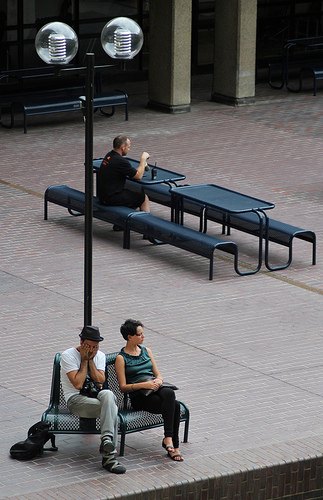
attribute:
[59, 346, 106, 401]
shirt — short sleeve, white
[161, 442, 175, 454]
sandal — open toed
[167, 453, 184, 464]
sandal — open toed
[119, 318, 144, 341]
hair — black, dark, short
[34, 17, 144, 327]
lamp post — black, tall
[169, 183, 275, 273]
table — picnic table, metal, green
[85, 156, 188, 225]
table — metal, green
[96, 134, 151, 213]
man — sitting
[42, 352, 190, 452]
bench — metal, black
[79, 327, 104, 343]
hat — black, fedora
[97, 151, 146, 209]
clothing — dark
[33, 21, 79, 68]
globe — lamp, glass, round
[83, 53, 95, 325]
post — metal, black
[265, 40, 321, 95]
bicycle rack — metal, black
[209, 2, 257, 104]
support column — concrete, gray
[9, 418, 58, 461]
backpack — black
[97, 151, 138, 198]
shirt — short sleeve, black